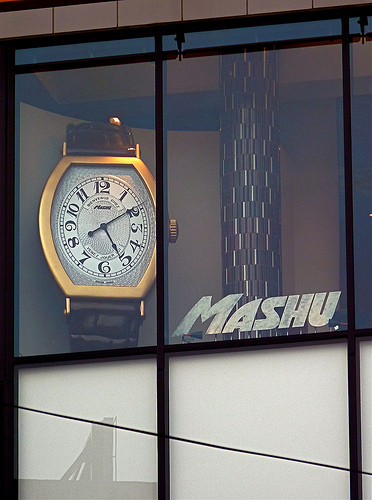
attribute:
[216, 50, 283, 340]
cylinder — black, gray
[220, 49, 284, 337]
column — gray, black, tall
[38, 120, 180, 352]
watch — white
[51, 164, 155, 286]
face — black, white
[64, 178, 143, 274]
numbers — cardinal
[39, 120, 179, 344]
large — watch, wrist watch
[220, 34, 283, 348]
pole — pillar, wide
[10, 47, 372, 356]
room — clear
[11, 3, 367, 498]
window — shiny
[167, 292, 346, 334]
name — writing, white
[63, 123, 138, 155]
strap — leather, brown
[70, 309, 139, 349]
strap — leather, brown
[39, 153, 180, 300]
gold — metallic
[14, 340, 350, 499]
window — white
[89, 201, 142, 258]
hand — brown